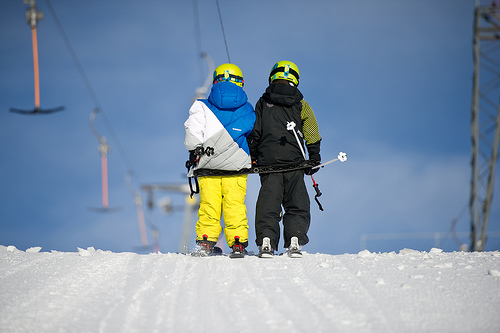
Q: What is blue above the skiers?
A: Sky.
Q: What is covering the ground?
A: Snow.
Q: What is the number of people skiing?
A: Two.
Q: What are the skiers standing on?
A: Snow.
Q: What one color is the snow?
A: White.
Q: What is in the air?
A: A ski lift.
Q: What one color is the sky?
A: Blue.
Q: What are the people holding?
A: Ski poles.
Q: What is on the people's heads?
A: Helmets.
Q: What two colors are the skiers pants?
A: Black and yellow.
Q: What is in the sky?
A: Clouds.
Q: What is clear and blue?
A: The sky.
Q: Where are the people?
A: On the ground.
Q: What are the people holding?
A: Ski poles.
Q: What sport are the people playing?
A: Skiing.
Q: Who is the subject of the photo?
A: The skiers.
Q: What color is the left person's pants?
A: Yellow.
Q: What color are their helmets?
A: Yellow.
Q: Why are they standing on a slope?
A: They are skiing.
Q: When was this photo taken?
A: During the day.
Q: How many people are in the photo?
A: 2.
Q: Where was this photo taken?
A: At a ski resort.